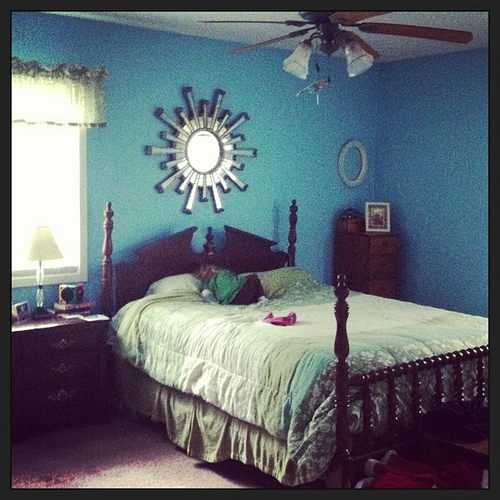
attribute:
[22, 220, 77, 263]
lamp shade — white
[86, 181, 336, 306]
headboard — brown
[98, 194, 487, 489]
bed — brown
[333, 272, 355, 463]
wooden post — brown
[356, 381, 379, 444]
wooden post — brown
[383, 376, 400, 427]
wooden post — brown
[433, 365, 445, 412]
wooden post — brown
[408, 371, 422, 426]
wooden post — brown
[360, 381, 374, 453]
wooden post — brown 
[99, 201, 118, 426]
post — wood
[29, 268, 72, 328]
base — clear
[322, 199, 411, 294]
cabinet — wooden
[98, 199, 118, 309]
wooden post — brown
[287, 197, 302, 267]
wooden post — brown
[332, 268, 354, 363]
wooden post — brown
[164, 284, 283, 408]
bedspread — light, colored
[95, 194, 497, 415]
wood-framed bed — wood framed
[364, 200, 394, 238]
frame — picture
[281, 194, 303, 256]
post — wood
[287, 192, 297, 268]
post — wood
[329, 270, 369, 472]
post — brown, wooden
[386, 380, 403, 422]
wooden post — brown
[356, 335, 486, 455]
footboard — wooden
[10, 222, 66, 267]
lamp shade — white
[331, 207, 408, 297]
dresser — small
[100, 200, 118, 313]
post — brown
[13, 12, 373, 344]
wall — blue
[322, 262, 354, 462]
post — brown, wooden